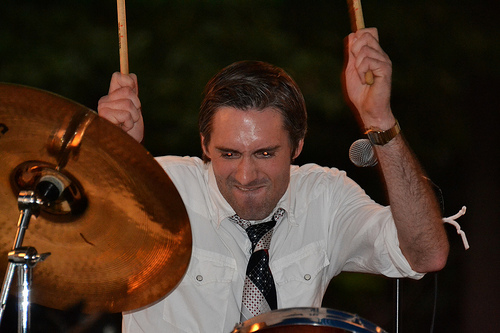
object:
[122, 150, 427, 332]
shirt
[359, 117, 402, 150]
watch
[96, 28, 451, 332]
man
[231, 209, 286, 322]
necktie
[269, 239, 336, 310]
pocket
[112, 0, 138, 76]
drumstick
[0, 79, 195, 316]
cymbal